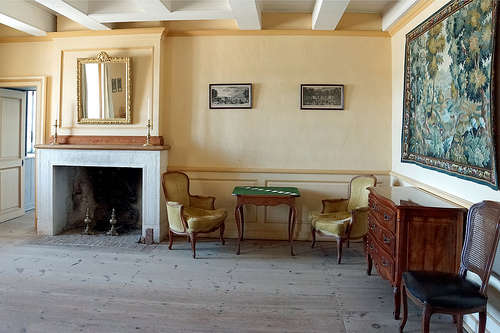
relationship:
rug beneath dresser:
[12, 199, 447, 326] [356, 172, 472, 328]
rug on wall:
[12, 259, 365, 333] [168, 115, 392, 186]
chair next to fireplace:
[147, 167, 239, 265] [27, 117, 161, 257]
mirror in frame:
[80, 62, 126, 121] [81, 116, 136, 134]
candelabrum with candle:
[142, 119, 154, 147] [145, 118, 155, 126]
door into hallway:
[0, 84, 22, 226] [4, 99, 34, 230]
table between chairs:
[228, 172, 302, 275] [149, 163, 380, 282]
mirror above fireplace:
[69, 60, 150, 128] [28, 130, 167, 257]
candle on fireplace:
[148, 98, 151, 119] [25, 123, 166, 241]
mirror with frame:
[80, 62, 126, 121] [77, 118, 137, 132]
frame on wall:
[208, 83, 252, 109] [166, 136, 396, 333]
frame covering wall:
[208, 83, 252, 109] [165, 80, 391, 187]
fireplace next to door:
[33, 144, 161, 244] [0, 98, 36, 233]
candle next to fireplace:
[138, 114, 174, 154] [34, 132, 167, 241]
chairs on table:
[162, 146, 381, 276] [223, 168, 303, 259]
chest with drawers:
[357, 170, 466, 333] [360, 194, 410, 282]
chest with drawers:
[362, 186, 467, 320] [364, 192, 403, 277]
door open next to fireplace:
[0, 88, 27, 224] [35, 144, 171, 242]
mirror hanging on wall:
[80, 62, 126, 121] [0, 33, 391, 242]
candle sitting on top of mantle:
[148, 98, 151, 119] [33, 142, 171, 148]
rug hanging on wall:
[398, 0, 485, 190] [390, 1, 483, 319]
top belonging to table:
[230, 184, 300, 199] [230, 184, 301, 257]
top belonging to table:
[232, 186, 300, 196] [230, 184, 301, 257]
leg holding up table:
[232, 200, 243, 255] [230, 184, 301, 257]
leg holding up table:
[239, 205, 246, 245] [230, 184, 301, 257]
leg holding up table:
[287, 202, 297, 257] [230, 184, 301, 257]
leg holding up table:
[285, 205, 293, 244] [230, 184, 301, 257]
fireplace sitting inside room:
[35, 144, 171, 242] [1, 1, 480, 331]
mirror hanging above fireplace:
[80, 62, 126, 121] [35, 144, 171, 242]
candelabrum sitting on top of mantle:
[50, 100, 61, 146] [32, 142, 170, 151]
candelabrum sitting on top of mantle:
[142, 93, 154, 147] [34, 141, 173, 151]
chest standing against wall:
[362, 186, 467, 320] [390, 1, 483, 319]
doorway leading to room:
[1, 76, 47, 232] [1, 1, 480, 331]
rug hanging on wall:
[400, 0, 500, 192] [390, 1, 483, 319]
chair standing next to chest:
[395, 198, 485, 329] [362, 186, 467, 320]